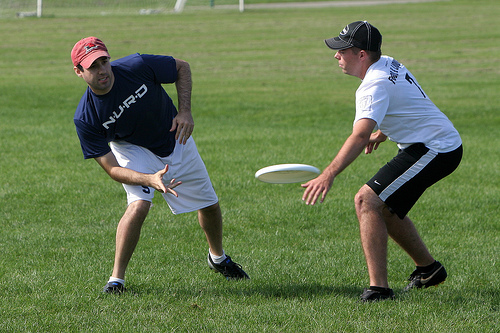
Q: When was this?
A: Daytime.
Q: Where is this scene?
A: Park.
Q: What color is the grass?
A: Green.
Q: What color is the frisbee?
A: White.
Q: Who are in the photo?
A: People.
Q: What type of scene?
A: Outdoor.